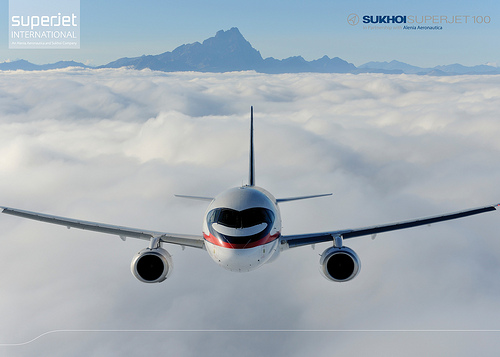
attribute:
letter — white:
[70, 11, 80, 28]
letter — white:
[60, 14, 71, 28]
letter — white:
[48, 12, 58, 30]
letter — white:
[30, 15, 41, 32]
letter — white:
[9, 13, 23, 29]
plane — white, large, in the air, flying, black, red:
[1, 104, 500, 283]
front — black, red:
[201, 207, 282, 249]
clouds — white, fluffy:
[0, 73, 173, 204]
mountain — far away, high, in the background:
[98, 26, 264, 66]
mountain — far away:
[365, 58, 500, 73]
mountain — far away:
[261, 53, 355, 66]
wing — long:
[0, 205, 207, 251]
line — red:
[200, 232, 279, 249]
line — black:
[207, 207, 276, 245]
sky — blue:
[82, 3, 167, 50]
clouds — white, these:
[273, 78, 495, 189]